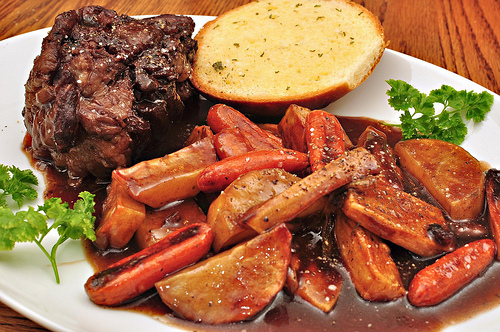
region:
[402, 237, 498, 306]
A little weenie in the brown sauce on the bottom right.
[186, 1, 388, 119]
A brown and yellow bun lying on the plate.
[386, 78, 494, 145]
A sprig of green leaves to the right of a bun.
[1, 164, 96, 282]
A bigger lighter green sprig of leaves.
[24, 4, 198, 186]
A giant brown lump of meat.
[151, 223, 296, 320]
The largest chunk of potato on the bottom.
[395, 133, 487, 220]
Large chunk of potato beside the darker leaf.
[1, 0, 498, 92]
Brown table all above and around the top of the plate.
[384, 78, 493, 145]
Darker upper green leaves.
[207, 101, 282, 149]
Middle orange carrot touching a bun.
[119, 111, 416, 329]
the sauce is brown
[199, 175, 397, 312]
the sauce is brown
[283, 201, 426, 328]
the sauce is brown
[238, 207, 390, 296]
the sauce is brown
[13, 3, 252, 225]
the meat is brown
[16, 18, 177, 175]
the meat is brown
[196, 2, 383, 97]
a piece of bread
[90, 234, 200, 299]
a piece of stewed carrot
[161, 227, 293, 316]
a piece of stewed potato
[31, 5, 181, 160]
a piece of pork meat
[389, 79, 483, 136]
a decorative green leaf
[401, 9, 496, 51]
part of a brown table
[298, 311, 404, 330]
this is a brown sauce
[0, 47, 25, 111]
part of a white plate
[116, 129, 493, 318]
potatoes and carrots together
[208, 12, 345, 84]
butter spread on the bread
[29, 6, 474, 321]
Plate full of food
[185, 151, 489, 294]
Pieces of potato on plate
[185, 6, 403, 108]
Small slice of garlic bread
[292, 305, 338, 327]
Sauce on plate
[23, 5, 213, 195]
Portion of meat on the side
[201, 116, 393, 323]
Carrots that have been stewed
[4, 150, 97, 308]
Parsley on side of plate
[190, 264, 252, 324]
Spices on the potato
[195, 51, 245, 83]
Italian spice on bread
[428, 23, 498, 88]
Table is made of wood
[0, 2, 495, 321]
A large plate of food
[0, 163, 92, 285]
A green garnish by the side of the plate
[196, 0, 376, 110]
A piece of garlic toast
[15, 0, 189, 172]
A large hunk of meat on the plate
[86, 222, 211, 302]
A small grilled sausage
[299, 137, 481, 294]
Wedges of potatoes in a sauce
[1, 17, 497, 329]
A long white plate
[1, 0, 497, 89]
A wooden table beneath the plate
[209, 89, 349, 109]
The underside of the toast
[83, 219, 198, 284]
Grill marks on the sausage